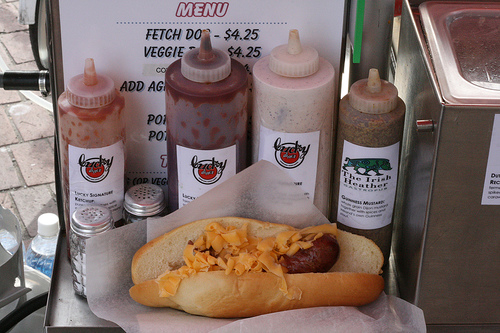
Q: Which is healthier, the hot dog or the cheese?
A: The cheese is healthier than the hot dog.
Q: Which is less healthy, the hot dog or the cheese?
A: The hot dog is less healthy than the cheese.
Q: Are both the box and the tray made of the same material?
A: Yes, both the box and the tray are made of metal.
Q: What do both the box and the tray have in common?
A: The material, both the box and the tray are metallic.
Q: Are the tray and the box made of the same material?
A: Yes, both the tray and the box are made of metal.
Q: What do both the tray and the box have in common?
A: The material, both the tray and the box are metallic.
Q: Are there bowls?
A: No, there are no bowls.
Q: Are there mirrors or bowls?
A: No, there are no bowls or mirrors.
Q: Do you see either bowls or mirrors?
A: No, there are no bowls or mirrors.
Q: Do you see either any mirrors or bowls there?
A: No, there are no bowls or mirrors.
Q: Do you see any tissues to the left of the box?
A: Yes, there is a tissue to the left of the box.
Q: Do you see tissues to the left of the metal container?
A: Yes, there is a tissue to the left of the box.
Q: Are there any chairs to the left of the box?
A: No, there is a tissue to the left of the box.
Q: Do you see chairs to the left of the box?
A: No, there is a tissue to the left of the box.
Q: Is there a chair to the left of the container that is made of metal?
A: No, there is a tissue to the left of the box.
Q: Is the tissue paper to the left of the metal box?
A: Yes, the tissue paper is to the left of the box.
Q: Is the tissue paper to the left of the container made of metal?
A: Yes, the tissue paper is to the left of the box.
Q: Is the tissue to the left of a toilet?
A: No, the tissue is to the left of the box.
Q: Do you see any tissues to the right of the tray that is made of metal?
A: Yes, there is a tissue to the right of the tray.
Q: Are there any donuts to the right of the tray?
A: No, there is a tissue to the right of the tray.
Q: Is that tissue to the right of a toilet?
A: No, the tissue is to the right of the tray.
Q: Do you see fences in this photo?
A: No, there are no fences.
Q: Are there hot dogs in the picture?
A: Yes, there is a hot dog.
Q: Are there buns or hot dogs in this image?
A: Yes, there is a hot dog.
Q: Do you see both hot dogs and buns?
A: Yes, there are both a hot dog and a bun.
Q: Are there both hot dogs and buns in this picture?
A: Yes, there are both a hot dog and a bun.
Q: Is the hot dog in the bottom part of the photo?
A: Yes, the hot dog is in the bottom of the image.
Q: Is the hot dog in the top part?
A: No, the hot dog is in the bottom of the image.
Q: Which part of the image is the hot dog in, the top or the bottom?
A: The hot dog is in the bottom of the image.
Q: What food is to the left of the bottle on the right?
A: The food is a hot dog.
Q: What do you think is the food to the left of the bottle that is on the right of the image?
A: The food is a hot dog.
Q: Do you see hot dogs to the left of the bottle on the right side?
A: Yes, there is a hot dog to the left of the bottle.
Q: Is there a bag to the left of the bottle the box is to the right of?
A: No, there is a hot dog to the left of the bottle.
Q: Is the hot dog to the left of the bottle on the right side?
A: Yes, the hot dog is to the left of the bottle.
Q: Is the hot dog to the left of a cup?
A: No, the hot dog is to the left of the bottle.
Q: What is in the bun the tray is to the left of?
A: The hot dog is in the bun.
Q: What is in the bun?
A: The hot dog is in the bun.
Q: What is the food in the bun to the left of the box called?
A: The food is a hot dog.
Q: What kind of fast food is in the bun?
A: The food is a hot dog.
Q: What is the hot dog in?
A: The hot dog is in the bun.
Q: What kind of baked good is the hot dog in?
A: The hot dog is in the bun.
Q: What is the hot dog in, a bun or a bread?
A: The hot dog is in a bun.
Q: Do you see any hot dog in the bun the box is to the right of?
A: Yes, there is a hot dog in the bun.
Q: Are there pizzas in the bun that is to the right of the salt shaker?
A: No, there is a hot dog in the bun.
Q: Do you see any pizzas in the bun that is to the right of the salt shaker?
A: No, there is a hot dog in the bun.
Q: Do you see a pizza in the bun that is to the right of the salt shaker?
A: No, there is a hot dog in the bun.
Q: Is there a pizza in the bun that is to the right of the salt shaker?
A: No, there is a hot dog in the bun.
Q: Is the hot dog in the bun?
A: Yes, the hot dog is in the bun.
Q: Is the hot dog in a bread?
A: No, the hot dog is in the bun.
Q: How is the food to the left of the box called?
A: The food is a hot dog.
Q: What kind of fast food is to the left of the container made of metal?
A: The food is a hot dog.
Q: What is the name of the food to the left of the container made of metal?
A: The food is a hot dog.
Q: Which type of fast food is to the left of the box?
A: The food is a hot dog.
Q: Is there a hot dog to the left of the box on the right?
A: Yes, there is a hot dog to the left of the box.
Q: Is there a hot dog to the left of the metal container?
A: Yes, there is a hot dog to the left of the box.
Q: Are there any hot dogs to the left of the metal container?
A: Yes, there is a hot dog to the left of the box.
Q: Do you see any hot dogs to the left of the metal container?
A: Yes, there is a hot dog to the left of the box.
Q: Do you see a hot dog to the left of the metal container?
A: Yes, there is a hot dog to the left of the box.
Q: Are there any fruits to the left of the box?
A: No, there is a hot dog to the left of the box.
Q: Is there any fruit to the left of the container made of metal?
A: No, there is a hot dog to the left of the box.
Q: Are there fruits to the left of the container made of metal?
A: No, there is a hot dog to the left of the box.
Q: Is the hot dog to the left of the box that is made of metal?
A: Yes, the hot dog is to the left of the box.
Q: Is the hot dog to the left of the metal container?
A: Yes, the hot dog is to the left of the box.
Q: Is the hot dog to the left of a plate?
A: No, the hot dog is to the left of the box.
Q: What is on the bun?
A: The hot dog is on the bun.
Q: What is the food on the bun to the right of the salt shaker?
A: The food is a hot dog.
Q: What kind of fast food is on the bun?
A: The food is a hot dog.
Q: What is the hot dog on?
A: The hot dog is on the bun.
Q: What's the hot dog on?
A: The hot dog is on the bun.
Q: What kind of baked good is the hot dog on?
A: The hot dog is on the bun.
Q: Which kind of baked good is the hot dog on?
A: The hot dog is on the bun.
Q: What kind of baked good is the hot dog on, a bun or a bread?
A: The hot dog is on a bun.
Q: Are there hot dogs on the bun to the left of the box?
A: Yes, there is a hot dog on the bun.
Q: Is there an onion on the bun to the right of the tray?
A: No, there is a hot dog on the bun.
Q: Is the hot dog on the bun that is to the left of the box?
A: Yes, the hot dog is on the bun.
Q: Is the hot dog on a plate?
A: No, the hot dog is on the bun.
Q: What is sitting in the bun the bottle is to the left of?
A: The hot dog is sitting in the bun.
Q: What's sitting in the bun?
A: The hot dog is sitting in the bun.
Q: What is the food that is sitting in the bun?
A: The food is a hot dog.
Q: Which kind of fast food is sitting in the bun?
A: The food is a hot dog.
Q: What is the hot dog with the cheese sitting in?
A: The hot dog is sitting in the bun.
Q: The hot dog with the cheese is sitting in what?
A: The hot dog is sitting in the bun.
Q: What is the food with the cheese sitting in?
A: The hot dog is sitting in the bun.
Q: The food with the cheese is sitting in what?
A: The hot dog is sitting in the bun.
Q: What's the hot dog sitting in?
A: The hot dog is sitting in the bun.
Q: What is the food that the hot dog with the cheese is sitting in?
A: The food is a bun.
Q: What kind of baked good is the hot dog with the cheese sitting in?
A: The hot dog is sitting in the bun.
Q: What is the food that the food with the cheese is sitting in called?
A: The food is a bun.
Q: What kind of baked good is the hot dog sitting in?
A: The hot dog is sitting in the bun.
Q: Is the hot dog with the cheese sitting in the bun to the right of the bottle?
A: Yes, the hot dog is sitting in the bun.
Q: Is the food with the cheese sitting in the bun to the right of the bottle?
A: Yes, the hot dog is sitting in the bun.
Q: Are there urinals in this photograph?
A: No, there are no urinals.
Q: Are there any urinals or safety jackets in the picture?
A: No, there are no urinals or safety jackets.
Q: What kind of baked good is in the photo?
A: The baked good is a bun.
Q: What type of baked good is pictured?
A: The baked good is a bun.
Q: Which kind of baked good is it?
A: The food is a bun.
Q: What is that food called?
A: This is a bun.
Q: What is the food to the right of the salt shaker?
A: The food is a bun.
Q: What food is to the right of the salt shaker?
A: The food is a bun.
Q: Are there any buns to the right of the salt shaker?
A: Yes, there is a bun to the right of the salt shaker.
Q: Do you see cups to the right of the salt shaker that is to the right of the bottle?
A: No, there is a bun to the right of the salt shaker.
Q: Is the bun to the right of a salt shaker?
A: Yes, the bun is to the right of a salt shaker.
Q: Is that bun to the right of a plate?
A: No, the bun is to the right of a salt shaker.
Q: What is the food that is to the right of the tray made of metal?
A: The food is a bun.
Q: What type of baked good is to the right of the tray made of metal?
A: The food is a bun.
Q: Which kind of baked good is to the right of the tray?
A: The food is a bun.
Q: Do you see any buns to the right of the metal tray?
A: Yes, there is a bun to the right of the tray.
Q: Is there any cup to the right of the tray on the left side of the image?
A: No, there is a bun to the right of the tray.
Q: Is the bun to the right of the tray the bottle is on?
A: Yes, the bun is to the right of the tray.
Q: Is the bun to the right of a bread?
A: No, the bun is to the right of the tray.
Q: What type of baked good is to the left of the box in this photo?
A: The food is a bun.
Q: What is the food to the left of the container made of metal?
A: The food is a bun.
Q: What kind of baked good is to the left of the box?
A: The food is a bun.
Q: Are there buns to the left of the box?
A: Yes, there is a bun to the left of the box.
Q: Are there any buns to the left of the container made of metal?
A: Yes, there is a bun to the left of the box.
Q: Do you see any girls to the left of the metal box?
A: No, there is a bun to the left of the box.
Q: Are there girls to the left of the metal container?
A: No, there is a bun to the left of the box.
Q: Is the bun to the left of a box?
A: Yes, the bun is to the left of a box.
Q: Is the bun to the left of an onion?
A: No, the bun is to the left of a box.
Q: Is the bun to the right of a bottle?
A: Yes, the bun is to the right of a bottle.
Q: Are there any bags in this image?
A: No, there are no bags.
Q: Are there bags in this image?
A: No, there are no bags.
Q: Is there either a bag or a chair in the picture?
A: No, there are no bags or chairs.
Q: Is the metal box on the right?
A: Yes, the box is on the right of the image.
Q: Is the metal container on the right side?
A: Yes, the box is on the right of the image.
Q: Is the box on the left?
A: No, the box is on the right of the image.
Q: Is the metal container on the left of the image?
A: No, the box is on the right of the image.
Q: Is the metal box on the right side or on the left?
A: The box is on the right of the image.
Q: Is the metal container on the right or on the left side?
A: The box is on the right of the image.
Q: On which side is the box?
A: The box is on the right of the image.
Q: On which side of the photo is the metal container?
A: The box is on the right of the image.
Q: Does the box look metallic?
A: Yes, the box is metallic.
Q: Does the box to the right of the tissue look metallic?
A: Yes, the box is metallic.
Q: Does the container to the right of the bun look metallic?
A: Yes, the box is metallic.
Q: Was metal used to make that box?
A: Yes, the box is made of metal.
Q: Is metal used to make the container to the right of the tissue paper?
A: Yes, the box is made of metal.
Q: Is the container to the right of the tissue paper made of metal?
A: Yes, the box is made of metal.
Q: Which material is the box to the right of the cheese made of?
A: The box is made of metal.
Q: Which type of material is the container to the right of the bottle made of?
A: The box is made of metal.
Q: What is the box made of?
A: The box is made of metal.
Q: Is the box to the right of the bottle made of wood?
A: No, the box is made of metal.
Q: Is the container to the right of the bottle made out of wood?
A: No, the box is made of metal.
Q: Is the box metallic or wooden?
A: The box is metallic.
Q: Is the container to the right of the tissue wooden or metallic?
A: The box is metallic.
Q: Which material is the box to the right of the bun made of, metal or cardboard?
A: The box is made of metal.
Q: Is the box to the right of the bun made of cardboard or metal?
A: The box is made of metal.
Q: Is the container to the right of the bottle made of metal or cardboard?
A: The box is made of metal.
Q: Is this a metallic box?
A: Yes, this is a metallic box.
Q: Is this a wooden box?
A: No, this is a metallic box.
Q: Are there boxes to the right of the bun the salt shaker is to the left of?
A: Yes, there is a box to the right of the bun.